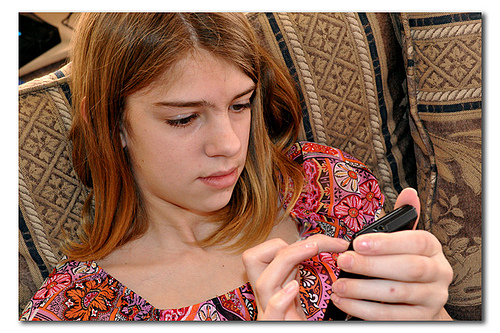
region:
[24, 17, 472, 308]
girl texting on couch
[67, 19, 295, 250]
brown hair of girl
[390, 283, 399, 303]
ouchy on the left ring finger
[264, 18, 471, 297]
tan black and white designed couch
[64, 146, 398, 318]
multi colored multi designed peasant shirt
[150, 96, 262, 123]
set of dark brown eyes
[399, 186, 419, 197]
well groomed thumb nail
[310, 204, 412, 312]
black slightly older smart phone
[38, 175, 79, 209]
de fleur design in black and tan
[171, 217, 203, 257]
one of those boney things sticking out of her neck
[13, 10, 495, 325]
girl wearing a paisley shirt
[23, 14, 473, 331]
girl wearing a pink and orange shirt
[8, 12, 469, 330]
girl with brown hair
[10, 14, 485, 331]
girl with medium length hair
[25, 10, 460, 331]
girl looking at her cellphone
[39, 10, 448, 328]
girl on her cellphone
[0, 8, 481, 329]
girl leaning on a pillow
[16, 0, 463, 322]
girl with straight hair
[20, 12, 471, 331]
girl with thick eyebrows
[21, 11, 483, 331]
girl typing on her phone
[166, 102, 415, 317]
The girl is looking at a cell phone.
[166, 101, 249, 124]
Two eyes are open and brown.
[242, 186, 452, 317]
Two hands are holding a cell phone.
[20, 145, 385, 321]
The girl is wearing a colorful dress.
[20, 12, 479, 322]
The girl is leaning on cushions.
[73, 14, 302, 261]
A girl has brown hair with dark highlights.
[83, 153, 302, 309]
The dress ends below the collar bones.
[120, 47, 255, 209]
The face is looking down and to her left.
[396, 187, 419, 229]
A thumb is sticking out above the black object.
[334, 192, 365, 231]
A red and white flower has a orange and white dot in middle.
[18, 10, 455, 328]
girl is looking at phone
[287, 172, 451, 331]
the phone is black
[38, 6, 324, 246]
girl's hair is brown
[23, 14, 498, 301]
pillows are behind girl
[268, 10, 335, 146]
black line on pillow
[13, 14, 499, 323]
the pillows are brown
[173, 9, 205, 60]
girl's hair is parted in middle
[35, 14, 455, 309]
girl is leaning back on pillows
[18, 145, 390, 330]
girl's shirt is pink and orange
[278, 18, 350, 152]
white lines on pillow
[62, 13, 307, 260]
girl has red hair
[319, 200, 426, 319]
the phone is black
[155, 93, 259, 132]
her eyes are dark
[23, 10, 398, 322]
her shirt is multicolored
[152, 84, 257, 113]
her eyebrows are growing together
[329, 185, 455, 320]
she has a mark on her finger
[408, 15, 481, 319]
the cushion is ugly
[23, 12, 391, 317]
her shirt has orange in it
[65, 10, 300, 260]
her hair has a blonde tint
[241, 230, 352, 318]
her finger is crooked